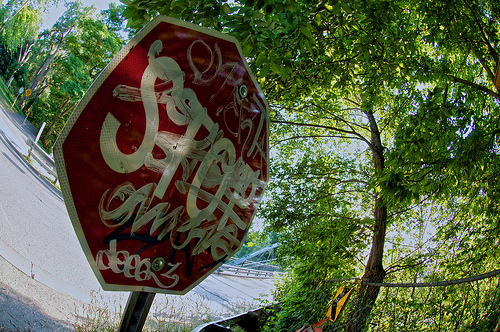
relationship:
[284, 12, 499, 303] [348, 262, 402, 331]
tree has trunk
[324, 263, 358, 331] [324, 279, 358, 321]
sign has sign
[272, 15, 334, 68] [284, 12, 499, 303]
leaves on tree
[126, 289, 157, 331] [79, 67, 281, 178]
pole on sign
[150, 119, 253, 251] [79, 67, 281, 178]
graffiti on sign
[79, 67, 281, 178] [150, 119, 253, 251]
sign has graffiti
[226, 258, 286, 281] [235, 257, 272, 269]
bridge over river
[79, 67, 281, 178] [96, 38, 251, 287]
sign has graffiti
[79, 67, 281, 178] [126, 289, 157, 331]
sign on pole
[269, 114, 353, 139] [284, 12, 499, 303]
branch on tree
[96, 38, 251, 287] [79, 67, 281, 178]
graffiti on sign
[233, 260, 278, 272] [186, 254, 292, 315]
guard rail on street